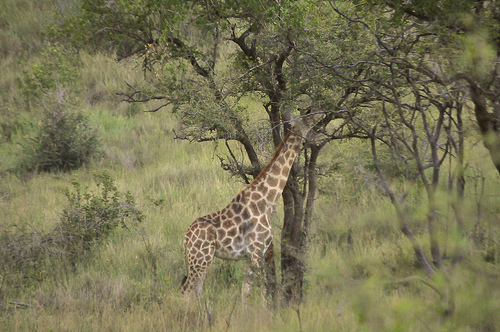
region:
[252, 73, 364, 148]
giraffe's head hidden by trees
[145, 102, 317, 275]
giraffe has brown spots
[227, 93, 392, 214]
the giraffe is eating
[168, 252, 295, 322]
grass is blocking giraffe's hooves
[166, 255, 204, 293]
giraffe's tail is behind it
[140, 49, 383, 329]
giraffe standing in front of tree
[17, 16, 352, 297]
giraffe is by itself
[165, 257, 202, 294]
giraffe's tail is black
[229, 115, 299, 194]
giraffe's mane hair is brown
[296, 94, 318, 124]
giraffe's eye is black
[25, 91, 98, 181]
a bush in the forest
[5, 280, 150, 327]
tall brown grass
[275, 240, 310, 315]
base of a tree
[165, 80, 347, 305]
a giraffe reaching into the trees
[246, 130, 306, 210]
the long neck of a giraffe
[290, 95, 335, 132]
giraffe's head hidden by foliage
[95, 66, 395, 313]
animal in its natural habitat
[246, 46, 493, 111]
trees in the woods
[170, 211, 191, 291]
black hair at the tip of the tail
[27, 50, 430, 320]
a giraffe feeding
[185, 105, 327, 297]
a giraffe with its head in a tree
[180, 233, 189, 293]
the tail of a giraffe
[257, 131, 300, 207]
the neck of a giraffe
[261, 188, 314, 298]
small trunk of a tree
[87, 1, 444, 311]
a girafee and a tree with many branches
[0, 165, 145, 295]
a small green bush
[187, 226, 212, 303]
hind leg of a giraffe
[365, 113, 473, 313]
leafless tree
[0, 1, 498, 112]
dense green foliage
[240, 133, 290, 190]
the mane of a giraffe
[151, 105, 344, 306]
giraffe with head in tree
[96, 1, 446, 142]
tree with green leaves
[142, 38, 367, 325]
giraffe eating leaves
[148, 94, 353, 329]
giraffe standing in tall grass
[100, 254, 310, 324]
tall dried brown grass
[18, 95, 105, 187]
bush with no leaves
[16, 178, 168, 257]
bush with green leaves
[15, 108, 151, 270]
bushes in tall dry grass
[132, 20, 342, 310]
giraffe reaching into tree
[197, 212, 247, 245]
brown spots on a giraffe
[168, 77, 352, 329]
a giraffe eating leaves from a tree.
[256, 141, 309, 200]
the neck of a giraffe.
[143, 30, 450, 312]
a tree with lots of brances.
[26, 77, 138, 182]
a green plant in a field.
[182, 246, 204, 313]
the hind leg of a giraffe.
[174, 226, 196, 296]
the tail on a giraffe.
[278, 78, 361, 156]
the head of a giraffe.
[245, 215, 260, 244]
spots on a giraffe.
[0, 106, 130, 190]
a green bush in a field.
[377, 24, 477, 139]
branches on a tree.